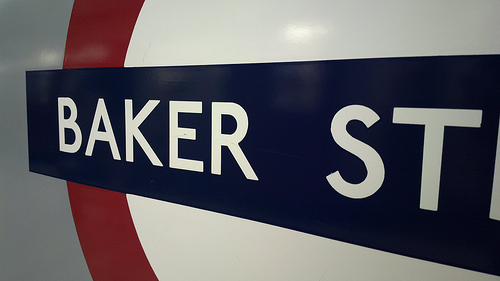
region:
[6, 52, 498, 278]
blue and white street sign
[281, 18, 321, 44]
light glare on the sign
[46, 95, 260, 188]
white writing in all caps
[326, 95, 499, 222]
white writing on a blue background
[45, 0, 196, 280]
curved red line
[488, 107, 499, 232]
part of a letter that was cut off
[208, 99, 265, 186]
capital R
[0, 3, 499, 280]
gray, red, white, and blue sign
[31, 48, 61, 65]
light glare on the gray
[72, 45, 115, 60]
light glare on the red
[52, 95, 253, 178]
"Baker" in white lettering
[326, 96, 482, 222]
"ST" in white lettering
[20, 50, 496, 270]
Blue strip on logo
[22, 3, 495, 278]
Blue, red and white logo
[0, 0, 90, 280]
Grey colored surface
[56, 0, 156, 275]
Red part of a circle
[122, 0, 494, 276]
Surface in the color of white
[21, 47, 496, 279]
Surface in the color of blue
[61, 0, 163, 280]
Surface in the color of red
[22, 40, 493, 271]
Sign that says Baker St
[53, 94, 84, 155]
A white letter B.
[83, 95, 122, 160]
A white letter A.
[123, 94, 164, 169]
A white letter K.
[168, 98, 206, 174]
A white letter E.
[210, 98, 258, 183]
A white letter R.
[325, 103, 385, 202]
A white letter S.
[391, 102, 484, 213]
A white letter T.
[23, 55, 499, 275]
A blue colored sign.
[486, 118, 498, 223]
A white letter on the sign.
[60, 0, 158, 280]
Red on the sign.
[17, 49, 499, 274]
sign that may say 'baker street' or 'baker station'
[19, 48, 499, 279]
print is in long navy blue rectangle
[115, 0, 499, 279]
main body of sign is white circle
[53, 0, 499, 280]
white circle is bordered by red circle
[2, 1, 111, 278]
background to sign is grey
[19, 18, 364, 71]
dashed light reflected over navy rectangle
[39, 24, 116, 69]
dashed light reflected both on red outlining circle & grey background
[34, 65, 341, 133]
reflected light slightly bleeds into navy rectangle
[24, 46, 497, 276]
white lettering, circle & rectangle clearly extend past the photo's right margin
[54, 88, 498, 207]
letters in white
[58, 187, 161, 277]
red stripe on white background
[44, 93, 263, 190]
"BAKER" on blue background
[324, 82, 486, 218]
"ST" on blue background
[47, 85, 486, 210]
"BAKER ST" on blue background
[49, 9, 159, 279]
part of a red circle on white background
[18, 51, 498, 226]
blue stripe on white background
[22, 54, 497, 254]
blue stripe with white text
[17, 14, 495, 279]
red, white and blue logo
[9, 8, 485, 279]
company logo in red, blue and white